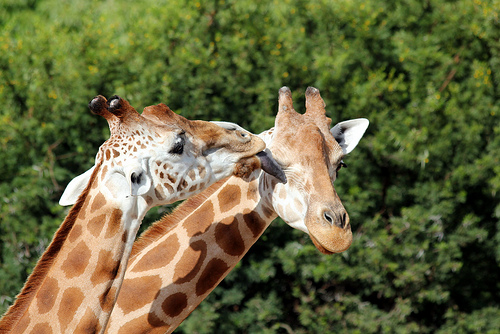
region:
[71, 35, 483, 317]
one giraffe licking another giraffe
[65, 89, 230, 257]
a giraffe with a very nice coat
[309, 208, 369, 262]
a giraffe's nose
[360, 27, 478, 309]
green and leafy trees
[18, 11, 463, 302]
two large animals in front of a densely wooded area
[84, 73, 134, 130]
two horny protrusions on an animals head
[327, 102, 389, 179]
a giraffe's large left ear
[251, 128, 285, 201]
a long purple tongue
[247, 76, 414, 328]
a large animal looking into the distance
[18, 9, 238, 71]
varigated green and yellow leaves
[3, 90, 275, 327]
giraffe licking the other giraffe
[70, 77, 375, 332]
giraffe being licked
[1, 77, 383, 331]
both of the giraffes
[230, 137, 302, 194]
tongue of giraffe licking other giraffe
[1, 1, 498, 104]
trees behind the giraffes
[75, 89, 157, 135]
antlers on giraffe licking the other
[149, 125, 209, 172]
eye of closest giraffe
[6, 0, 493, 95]
trees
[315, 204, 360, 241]
two giraffe nostrils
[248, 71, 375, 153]
antlers on giraffe facing forward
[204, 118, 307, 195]
A giraffe licking another giraffe's cheek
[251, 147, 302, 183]
A black protruding tongue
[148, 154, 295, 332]
Light and shadows playing on a giraffe's neck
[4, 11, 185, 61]
The sun shining on trees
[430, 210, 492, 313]
Dark shadows in the trees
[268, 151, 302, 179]
A giraffe's eye closing as his face is licked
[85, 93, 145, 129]
Black tipped giraffe horns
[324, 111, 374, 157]
The white inside of a giraffe's ear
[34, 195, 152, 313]
Spots mark the giraffe's neck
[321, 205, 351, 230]
A black patch between two nostrils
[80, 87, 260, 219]
a brown giraffe's head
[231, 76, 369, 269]
a brown giraffe's head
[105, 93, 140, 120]
a brown giraffe's horn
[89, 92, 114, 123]
a brown giraffe's horn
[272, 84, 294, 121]
a brown giraffe's horn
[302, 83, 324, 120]
a brown giraffe's horn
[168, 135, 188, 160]
a brown giraffe's eye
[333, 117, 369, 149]
a brown giraffe's ear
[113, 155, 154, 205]
a brown giraffe's ear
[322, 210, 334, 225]
a brown giraffe's nostril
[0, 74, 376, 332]
two giraffes next to each other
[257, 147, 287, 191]
the giraffes tongue is black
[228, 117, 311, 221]
the giraffe is licking the other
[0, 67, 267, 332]
the giraffe on the left has spots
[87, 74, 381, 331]
the giraffe on the right has spots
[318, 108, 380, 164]
the giraffe on the right has only one ear visible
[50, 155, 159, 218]
the giraffe on the left has white ears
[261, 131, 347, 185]
the giraffe on the right has its eyes closed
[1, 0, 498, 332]
the trees are green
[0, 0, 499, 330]
the trees are leafy